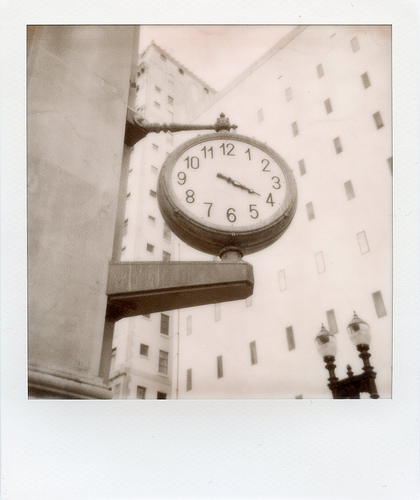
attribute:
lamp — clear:
[348, 308, 370, 345]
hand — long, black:
[215, 169, 262, 198]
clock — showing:
[155, 129, 299, 255]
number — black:
[255, 168, 309, 196]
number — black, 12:
[217, 138, 238, 159]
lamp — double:
[306, 298, 392, 389]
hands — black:
[215, 172, 266, 198]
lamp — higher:
[314, 309, 380, 399]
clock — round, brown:
[160, 123, 303, 251]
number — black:
[202, 201, 215, 217]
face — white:
[179, 146, 241, 211]